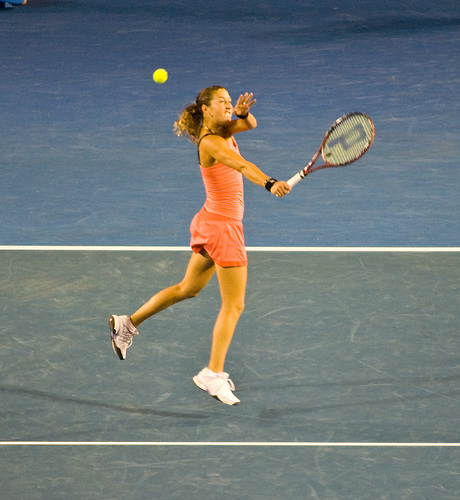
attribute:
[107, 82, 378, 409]
woman — jumping, white, player, tennis, caucasian, playing, off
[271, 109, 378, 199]
racket — tennis, yellow, maroon, moroon, red, white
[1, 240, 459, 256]
line — white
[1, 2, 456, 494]
court — tennis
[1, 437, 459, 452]
line — white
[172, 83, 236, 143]
hair — pony tail, brown, blonde, curly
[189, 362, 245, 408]
foot — tennis, white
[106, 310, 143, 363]
foot — tennis, white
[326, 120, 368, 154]
letter — p, blue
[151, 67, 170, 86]
ball — tennis, green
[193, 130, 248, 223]
top — tank, pink, colored, peach, athletic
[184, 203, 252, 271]
shorts — pink, peach, athletic, colored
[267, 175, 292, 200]
hand — rtigh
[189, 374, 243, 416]
soul — black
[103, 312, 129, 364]
soul — black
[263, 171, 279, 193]
band — black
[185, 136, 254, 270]
outfit — pink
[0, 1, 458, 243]
court — blue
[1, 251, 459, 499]
court — green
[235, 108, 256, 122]
band — black